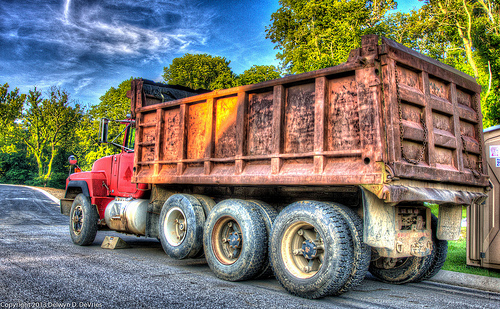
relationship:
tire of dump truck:
[68, 193, 97, 245] [60, 33, 490, 300]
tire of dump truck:
[158, 193, 204, 260] [60, 33, 490, 300]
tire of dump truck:
[268, 200, 353, 299] [60, 33, 490, 300]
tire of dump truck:
[203, 197, 267, 283] [60, 33, 490, 300]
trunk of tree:
[44, 148, 62, 178] [17, 89, 82, 183]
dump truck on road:
[60, 33, 490, 300] [1, 185, 499, 307]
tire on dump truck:
[68, 193, 97, 245] [60, 33, 490, 300]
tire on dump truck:
[158, 193, 204, 260] [60, 33, 490, 300]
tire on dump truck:
[203, 197, 267, 283] [60, 33, 490, 300]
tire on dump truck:
[268, 200, 353, 299] [60, 33, 490, 300]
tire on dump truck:
[324, 200, 372, 297] [60, 33, 490, 300]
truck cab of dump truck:
[65, 121, 147, 218] [60, 33, 490, 300]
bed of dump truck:
[129, 33, 490, 205] [60, 33, 490, 300]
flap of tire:
[361, 188, 401, 253] [324, 200, 372, 297]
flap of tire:
[436, 204, 465, 243] [368, 233, 438, 281]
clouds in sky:
[0, 0, 223, 74] [1, 1, 431, 131]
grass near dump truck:
[425, 202, 499, 277] [60, 33, 490, 300]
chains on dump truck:
[393, 60, 427, 164] [60, 33, 490, 300]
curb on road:
[0, 183, 499, 296] [1, 185, 499, 307]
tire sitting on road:
[203, 197, 267, 283] [1, 185, 499, 307]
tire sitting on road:
[268, 200, 353, 299] [1, 185, 499, 307]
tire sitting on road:
[324, 200, 372, 297] [1, 185, 499, 307]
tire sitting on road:
[368, 233, 438, 281] [1, 185, 499, 307]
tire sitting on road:
[358, 203, 451, 285] [1, 185, 499, 307]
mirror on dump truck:
[99, 118, 110, 145] [60, 33, 490, 300]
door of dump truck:
[119, 123, 138, 193] [60, 33, 490, 300]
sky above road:
[1, 1, 431, 131] [1, 185, 499, 307]